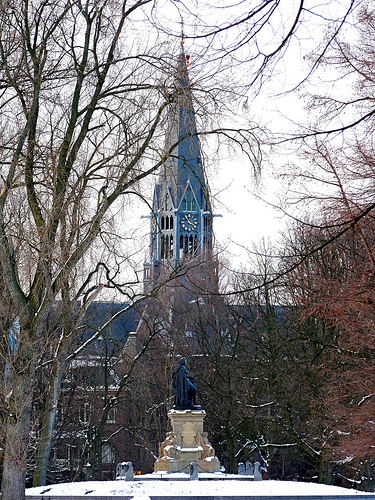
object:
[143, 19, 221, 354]
building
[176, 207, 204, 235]
clock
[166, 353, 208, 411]
statue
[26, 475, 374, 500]
snow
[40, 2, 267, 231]
tree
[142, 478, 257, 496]
snow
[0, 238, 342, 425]
trees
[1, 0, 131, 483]
trees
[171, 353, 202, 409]
statue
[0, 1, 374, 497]
town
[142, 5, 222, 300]
steeple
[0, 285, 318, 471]
church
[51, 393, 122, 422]
windows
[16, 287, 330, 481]
church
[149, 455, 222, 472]
base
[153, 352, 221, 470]
statue